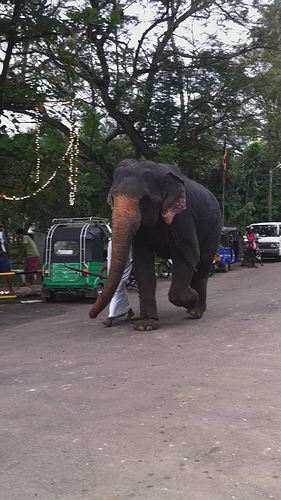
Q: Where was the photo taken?
A: It was taken at the road.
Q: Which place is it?
A: It is a road.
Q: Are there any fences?
A: No, there are no fences.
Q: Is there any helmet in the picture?
A: No, there are no helmets.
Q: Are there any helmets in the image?
A: No, there are no helmets.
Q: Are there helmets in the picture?
A: No, there are no helmets.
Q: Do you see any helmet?
A: No, there are no helmets.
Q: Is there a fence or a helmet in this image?
A: No, there are no helmets or fences.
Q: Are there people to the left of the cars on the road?
A: Yes, there is a person to the left of the cars.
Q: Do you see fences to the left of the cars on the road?
A: No, there is a person to the left of the cars.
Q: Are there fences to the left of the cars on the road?
A: No, there is a person to the left of the cars.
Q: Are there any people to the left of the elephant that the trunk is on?
A: Yes, there is a person to the left of the elephant.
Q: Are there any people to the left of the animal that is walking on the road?
A: Yes, there is a person to the left of the elephant.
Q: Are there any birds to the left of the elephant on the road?
A: No, there is a person to the left of the elephant.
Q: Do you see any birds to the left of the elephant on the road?
A: No, there is a person to the left of the elephant.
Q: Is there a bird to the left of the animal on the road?
A: No, there is a person to the left of the elephant.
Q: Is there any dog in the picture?
A: No, there are no dogs.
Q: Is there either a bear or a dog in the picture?
A: No, there are no dogs or bears.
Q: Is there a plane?
A: No, there are no airplanes.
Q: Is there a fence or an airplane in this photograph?
A: No, there are no airplanes or fences.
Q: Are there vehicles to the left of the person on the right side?
A: Yes, there is a vehicle to the left of the person.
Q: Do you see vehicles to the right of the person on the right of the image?
A: No, the vehicle is to the left of the person.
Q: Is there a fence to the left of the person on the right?
A: No, there is a vehicle to the left of the person.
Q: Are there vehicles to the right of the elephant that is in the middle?
A: Yes, there is a vehicle to the right of the elephant.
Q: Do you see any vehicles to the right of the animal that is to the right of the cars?
A: Yes, there is a vehicle to the right of the elephant.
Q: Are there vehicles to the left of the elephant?
A: No, the vehicle is to the right of the elephant.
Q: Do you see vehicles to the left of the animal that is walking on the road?
A: No, the vehicle is to the right of the elephant.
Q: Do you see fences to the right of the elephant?
A: No, there is a vehicle to the right of the elephant.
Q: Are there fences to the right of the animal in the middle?
A: No, there is a vehicle to the right of the elephant.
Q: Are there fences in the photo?
A: No, there are no fences.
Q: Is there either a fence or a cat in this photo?
A: No, there are no fences or cats.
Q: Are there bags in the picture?
A: No, there are no bags.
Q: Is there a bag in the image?
A: No, there are no bags.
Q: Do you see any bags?
A: No, there are no bags.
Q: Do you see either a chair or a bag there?
A: No, there are no bags or chairs.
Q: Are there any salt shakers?
A: No, there are no salt shakers.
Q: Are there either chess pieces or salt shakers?
A: No, there are no salt shakers or chess pieces.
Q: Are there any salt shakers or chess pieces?
A: No, there are no salt shakers or chess pieces.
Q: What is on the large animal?
A: The trunk is on the elephant.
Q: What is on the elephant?
A: The trunk is on the elephant.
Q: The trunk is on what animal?
A: The trunk is on the elephant.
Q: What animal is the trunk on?
A: The trunk is on the elephant.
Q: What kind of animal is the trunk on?
A: The trunk is on the elephant.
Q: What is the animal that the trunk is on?
A: The animal is an elephant.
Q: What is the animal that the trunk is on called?
A: The animal is an elephant.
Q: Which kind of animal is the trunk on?
A: The trunk is on the elephant.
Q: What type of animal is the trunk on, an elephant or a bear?
A: The trunk is on an elephant.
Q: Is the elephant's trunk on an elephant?
A: Yes, the trunk is on an elephant.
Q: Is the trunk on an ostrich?
A: No, the trunk is on an elephant.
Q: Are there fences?
A: No, there are no fences.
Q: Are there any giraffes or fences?
A: No, there are no fences or giraffes.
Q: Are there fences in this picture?
A: No, there are no fences.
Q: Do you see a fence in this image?
A: No, there are no fences.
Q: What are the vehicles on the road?
A: The vehicles are cars.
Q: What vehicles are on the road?
A: The vehicles are cars.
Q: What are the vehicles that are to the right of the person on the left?
A: The vehicles are cars.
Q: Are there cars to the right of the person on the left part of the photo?
A: Yes, there are cars to the right of the person.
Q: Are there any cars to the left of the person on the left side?
A: No, the cars are to the right of the person.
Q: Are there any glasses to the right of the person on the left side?
A: No, there are cars to the right of the person.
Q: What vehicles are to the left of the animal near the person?
A: The vehicles are cars.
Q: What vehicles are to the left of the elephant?
A: The vehicles are cars.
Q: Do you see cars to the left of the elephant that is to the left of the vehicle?
A: Yes, there are cars to the left of the elephant.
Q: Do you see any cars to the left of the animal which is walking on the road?
A: Yes, there are cars to the left of the elephant.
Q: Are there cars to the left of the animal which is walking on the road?
A: Yes, there are cars to the left of the elephant.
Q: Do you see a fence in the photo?
A: No, there are no fences.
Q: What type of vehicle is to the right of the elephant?
A: The vehicles are cars.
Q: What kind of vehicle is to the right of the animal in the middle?
A: The vehicles are cars.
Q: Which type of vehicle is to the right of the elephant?
A: The vehicles are cars.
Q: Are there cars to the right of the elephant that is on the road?
A: Yes, there are cars to the right of the elephant.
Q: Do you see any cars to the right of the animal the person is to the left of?
A: Yes, there are cars to the right of the elephant.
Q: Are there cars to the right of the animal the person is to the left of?
A: Yes, there are cars to the right of the elephant.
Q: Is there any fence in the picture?
A: No, there are no fences.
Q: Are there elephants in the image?
A: Yes, there is an elephant.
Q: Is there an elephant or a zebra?
A: Yes, there is an elephant.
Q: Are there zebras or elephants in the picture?
A: Yes, there is an elephant.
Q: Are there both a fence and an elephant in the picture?
A: No, there is an elephant but no fences.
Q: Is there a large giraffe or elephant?
A: Yes, there is a large elephant.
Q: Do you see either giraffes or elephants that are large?
A: Yes, the elephant is large.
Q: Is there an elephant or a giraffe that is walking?
A: Yes, the elephant is walking.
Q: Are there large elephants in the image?
A: Yes, there is a large elephant.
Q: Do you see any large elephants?
A: Yes, there is a large elephant.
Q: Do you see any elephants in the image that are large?
A: Yes, there is an elephant that is large.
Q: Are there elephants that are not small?
A: Yes, there is a large elephant.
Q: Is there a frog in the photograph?
A: No, there are no frogs.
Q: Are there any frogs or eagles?
A: No, there are no frogs or eagles.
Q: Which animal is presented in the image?
A: The animal is an elephant.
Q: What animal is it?
A: The animal is an elephant.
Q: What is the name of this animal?
A: This is an elephant.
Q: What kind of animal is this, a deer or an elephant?
A: This is an elephant.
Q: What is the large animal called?
A: The animal is an elephant.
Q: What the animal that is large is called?
A: The animal is an elephant.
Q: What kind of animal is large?
A: The animal is an elephant.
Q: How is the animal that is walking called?
A: The animal is an elephant.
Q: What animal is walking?
A: The animal is an elephant.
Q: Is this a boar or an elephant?
A: This is an elephant.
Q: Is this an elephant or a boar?
A: This is an elephant.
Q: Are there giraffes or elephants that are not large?
A: No, there is an elephant but it is large.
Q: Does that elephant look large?
A: Yes, the elephant is large.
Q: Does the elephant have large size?
A: Yes, the elephant is large.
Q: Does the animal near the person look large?
A: Yes, the elephant is large.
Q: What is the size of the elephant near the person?
A: The elephant is large.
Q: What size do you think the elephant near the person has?
A: The elephant has large size.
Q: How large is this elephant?
A: The elephant is large.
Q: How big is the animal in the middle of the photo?
A: The elephant is large.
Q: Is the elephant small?
A: No, the elephant is large.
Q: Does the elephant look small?
A: No, the elephant is large.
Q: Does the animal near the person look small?
A: No, the elephant is large.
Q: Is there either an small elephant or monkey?
A: No, there is an elephant but it is large.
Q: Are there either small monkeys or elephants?
A: No, there is an elephant but it is large.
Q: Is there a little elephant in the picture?
A: No, there is an elephant but it is large.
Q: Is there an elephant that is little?
A: No, there is an elephant but it is large.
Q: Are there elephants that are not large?
A: No, there is an elephant but it is large.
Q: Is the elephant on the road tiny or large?
A: The elephant is large.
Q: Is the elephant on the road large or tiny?
A: The elephant is large.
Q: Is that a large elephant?
A: Yes, that is a large elephant.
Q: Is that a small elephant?
A: No, that is a large elephant.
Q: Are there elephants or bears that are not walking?
A: No, there is an elephant but it is walking.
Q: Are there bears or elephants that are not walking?
A: No, there is an elephant but it is walking.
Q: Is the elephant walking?
A: Yes, the elephant is walking.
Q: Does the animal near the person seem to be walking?
A: Yes, the elephant is walking.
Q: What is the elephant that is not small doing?
A: The elephant is walking.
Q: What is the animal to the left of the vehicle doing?
A: The elephant is walking.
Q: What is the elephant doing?
A: The elephant is walking.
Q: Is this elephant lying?
A: No, the elephant is walking.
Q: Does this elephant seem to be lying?
A: No, the elephant is walking.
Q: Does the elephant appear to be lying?
A: No, the elephant is walking.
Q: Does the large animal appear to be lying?
A: No, the elephant is walking.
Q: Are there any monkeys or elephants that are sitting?
A: No, there is an elephant but it is walking.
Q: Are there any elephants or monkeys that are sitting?
A: No, there is an elephant but it is walking.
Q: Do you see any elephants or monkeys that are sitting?
A: No, there is an elephant but it is walking.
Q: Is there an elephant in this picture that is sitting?
A: No, there is an elephant but it is walking.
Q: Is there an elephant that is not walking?
A: No, there is an elephant but it is walking.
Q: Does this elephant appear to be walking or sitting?
A: The elephant is walking.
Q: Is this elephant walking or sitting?
A: The elephant is walking.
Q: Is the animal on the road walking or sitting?
A: The elephant is walking.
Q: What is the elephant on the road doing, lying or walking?
A: The elephant is walking.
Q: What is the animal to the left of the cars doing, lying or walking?
A: The elephant is walking.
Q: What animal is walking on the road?
A: The elephant is walking on the road.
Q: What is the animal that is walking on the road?
A: The animal is an elephant.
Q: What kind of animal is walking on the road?
A: The animal is an elephant.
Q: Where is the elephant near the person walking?
A: The elephant is walking on the road.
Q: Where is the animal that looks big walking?
A: The elephant is walking on the road.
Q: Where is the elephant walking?
A: The elephant is walking on the road.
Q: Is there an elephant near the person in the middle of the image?
A: Yes, there is an elephant near the person.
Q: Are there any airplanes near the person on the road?
A: No, there is an elephant near the person.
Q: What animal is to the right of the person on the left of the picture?
A: The animal is an elephant.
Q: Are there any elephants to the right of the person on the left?
A: Yes, there is an elephant to the right of the person.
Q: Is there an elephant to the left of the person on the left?
A: No, the elephant is to the right of the person.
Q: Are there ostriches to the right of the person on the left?
A: No, there is an elephant to the right of the person.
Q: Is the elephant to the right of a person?
A: Yes, the elephant is to the right of a person.